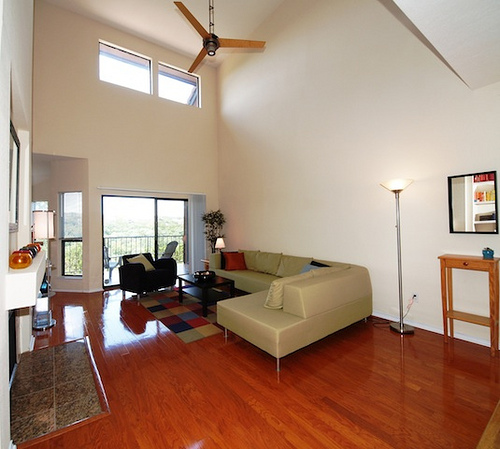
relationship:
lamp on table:
[209, 234, 230, 254] [197, 252, 215, 273]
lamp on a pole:
[373, 175, 418, 193] [388, 194, 416, 334]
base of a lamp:
[385, 319, 416, 336] [373, 175, 418, 193]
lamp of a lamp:
[215, 238, 227, 249] [373, 175, 418, 193]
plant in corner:
[192, 204, 226, 256] [201, 58, 239, 267]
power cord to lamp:
[370, 290, 428, 332] [373, 175, 418, 193]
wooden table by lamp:
[433, 249, 499, 357] [373, 175, 418, 193]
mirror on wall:
[441, 166, 499, 241] [215, 0, 500, 349]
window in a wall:
[93, 35, 209, 113] [32, 4, 217, 293]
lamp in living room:
[373, 175, 418, 193] [3, 1, 499, 448]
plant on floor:
[192, 204, 226, 256] [19, 292, 498, 448]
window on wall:
[50, 189, 86, 281] [32, 4, 217, 293]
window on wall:
[95, 191, 204, 287] [32, 4, 217, 293]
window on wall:
[31, 194, 56, 268] [32, 4, 217, 293]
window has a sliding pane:
[95, 191, 204, 287] [151, 194, 194, 277]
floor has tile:
[19, 292, 498, 448] [54, 396, 108, 431]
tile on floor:
[54, 396, 108, 431] [19, 292, 498, 448]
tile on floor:
[5, 388, 55, 426] [19, 292, 498, 448]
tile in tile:
[53, 358, 92, 386] [54, 396, 108, 431]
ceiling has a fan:
[34, 1, 303, 72] [170, 1, 269, 78]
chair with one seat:
[117, 250, 182, 295] [140, 266, 171, 278]